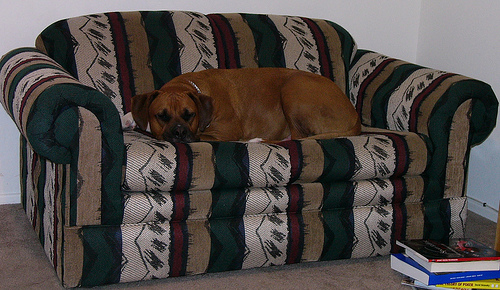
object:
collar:
[188, 80, 202, 94]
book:
[435, 279, 499, 290]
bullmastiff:
[130, 67, 362, 144]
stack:
[387, 236, 499, 290]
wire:
[466, 195, 500, 213]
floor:
[0, 202, 500, 290]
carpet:
[465, 208, 499, 255]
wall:
[418, 0, 499, 222]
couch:
[0, 10, 500, 290]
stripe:
[172, 142, 188, 277]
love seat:
[0, 10, 500, 290]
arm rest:
[347, 48, 499, 148]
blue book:
[390, 254, 499, 286]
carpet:
[89, 258, 411, 290]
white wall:
[0, 0, 422, 201]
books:
[405, 248, 500, 273]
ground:
[0, 204, 500, 290]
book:
[396, 238, 500, 263]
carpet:
[0, 203, 61, 290]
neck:
[159, 80, 203, 93]